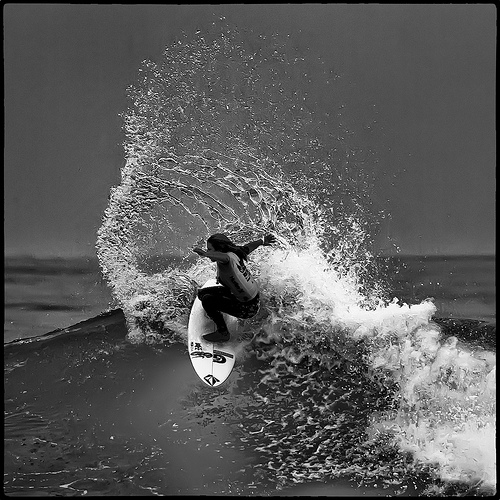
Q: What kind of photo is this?
A: Black and white.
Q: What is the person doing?
A: Surfing.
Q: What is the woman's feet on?
A: A surfboard.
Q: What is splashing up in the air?
A: Water.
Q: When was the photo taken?
A: During the daytime.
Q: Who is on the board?
A: A person.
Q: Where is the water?
A: Under the person.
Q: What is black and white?
A: The whole photo.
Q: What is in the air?
A: Water.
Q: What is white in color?
A: The board.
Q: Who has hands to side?
A: The woman.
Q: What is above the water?
A: The sky.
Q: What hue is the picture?
A: Black and white.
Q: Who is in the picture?
A: Surfer.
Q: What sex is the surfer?
A: Female.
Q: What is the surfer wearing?
A: Wet suit.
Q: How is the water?
A: Choppy.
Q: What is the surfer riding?
A: A wave.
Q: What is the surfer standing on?
A: A surfboard.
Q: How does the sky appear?
A: Black and gloomy.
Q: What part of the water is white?
A: Wave.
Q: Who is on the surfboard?
A: A man.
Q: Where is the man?
A: In the water.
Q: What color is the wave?
A: White.